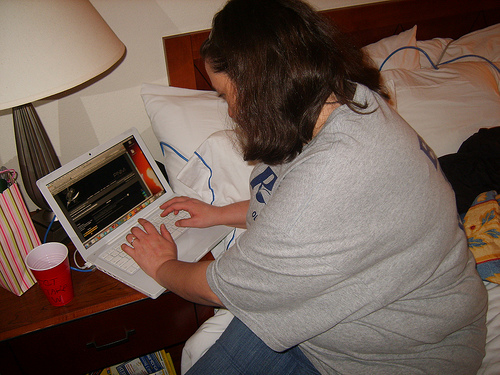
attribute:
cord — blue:
[393, 45, 483, 67]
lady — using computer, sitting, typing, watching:
[119, 1, 486, 375]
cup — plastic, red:
[25, 242, 76, 307]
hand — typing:
[121, 217, 220, 307]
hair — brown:
[194, 1, 391, 167]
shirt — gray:
[208, 80, 487, 374]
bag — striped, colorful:
[1, 168, 44, 296]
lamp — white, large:
[1, 3, 126, 230]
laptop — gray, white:
[36, 127, 234, 298]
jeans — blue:
[185, 318, 322, 373]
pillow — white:
[376, 60, 498, 157]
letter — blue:
[249, 165, 276, 203]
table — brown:
[5, 217, 216, 375]